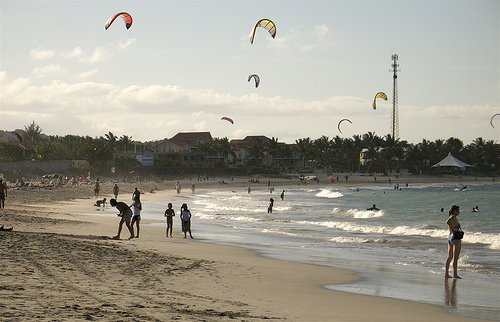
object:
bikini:
[446, 216, 464, 244]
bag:
[453, 229, 464, 240]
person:
[439, 198, 468, 282]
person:
[264, 197, 276, 216]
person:
[160, 201, 177, 237]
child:
[179, 203, 195, 239]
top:
[429, 151, 473, 168]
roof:
[170, 131, 215, 141]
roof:
[242, 135, 270, 140]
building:
[154, 131, 215, 167]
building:
[229, 135, 304, 174]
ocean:
[383, 188, 499, 240]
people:
[469, 204, 481, 212]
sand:
[9, 248, 243, 322]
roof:
[432, 152, 475, 168]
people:
[265, 197, 275, 213]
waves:
[335, 221, 444, 243]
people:
[129, 195, 143, 239]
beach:
[0, 195, 296, 322]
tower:
[385, 52, 406, 136]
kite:
[104, 11, 133, 31]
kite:
[487, 110, 500, 131]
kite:
[247, 73, 263, 88]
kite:
[218, 116, 235, 124]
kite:
[371, 90, 390, 108]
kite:
[336, 117, 353, 134]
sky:
[0, 0, 496, 127]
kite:
[247, 16, 280, 45]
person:
[365, 203, 381, 213]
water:
[311, 213, 441, 251]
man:
[108, 197, 133, 241]